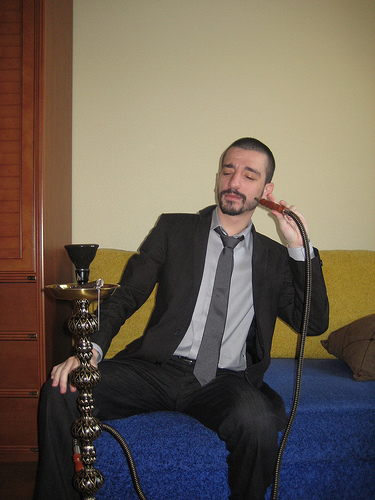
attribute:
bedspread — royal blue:
[96, 358, 374, 497]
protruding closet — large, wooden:
[2, 2, 74, 355]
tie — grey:
[192, 226, 243, 386]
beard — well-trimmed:
[216, 184, 264, 215]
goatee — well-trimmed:
[217, 186, 247, 217]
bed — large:
[67, 219, 374, 459]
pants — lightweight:
[44, 315, 316, 497]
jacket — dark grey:
[78, 201, 329, 411]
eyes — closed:
[234, 168, 264, 187]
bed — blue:
[60, 380, 373, 498]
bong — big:
[44, 244, 121, 499]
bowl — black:
[31, 232, 124, 496]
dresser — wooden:
[0, 274, 42, 459]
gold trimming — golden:
[45, 277, 131, 305]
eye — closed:
[211, 166, 273, 189]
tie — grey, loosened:
[192, 225, 248, 387]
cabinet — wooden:
[2, 1, 73, 491]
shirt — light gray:
[173, 204, 255, 371]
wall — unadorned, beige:
[160, 34, 283, 83]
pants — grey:
[33, 353, 280, 498]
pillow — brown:
[316, 310, 374, 387]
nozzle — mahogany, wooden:
[254, 193, 285, 212]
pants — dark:
[195, 364, 278, 442]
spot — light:
[322, 476, 333, 482]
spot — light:
[328, 446, 335, 458]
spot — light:
[359, 418, 369, 432]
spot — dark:
[318, 392, 327, 396]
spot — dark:
[187, 484, 195, 490]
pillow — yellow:
[69, 244, 373, 361]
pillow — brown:
[325, 313, 374, 379]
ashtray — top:
[41, 280, 122, 300]